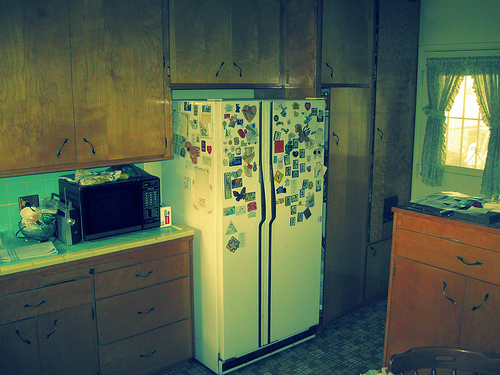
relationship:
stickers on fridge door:
[217, 111, 251, 203] [215, 96, 327, 343]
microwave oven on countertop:
[76, 171, 155, 236] [31, 233, 187, 254]